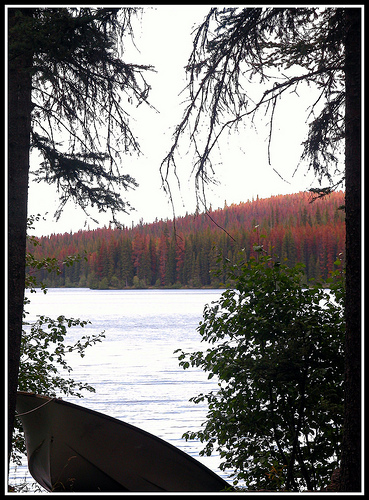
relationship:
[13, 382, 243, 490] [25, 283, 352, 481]
boat on side of lake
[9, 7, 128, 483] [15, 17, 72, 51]
trees have leaves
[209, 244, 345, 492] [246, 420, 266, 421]
bushes in background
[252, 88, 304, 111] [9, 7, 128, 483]
twigs from trees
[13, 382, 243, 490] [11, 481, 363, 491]
boat on shore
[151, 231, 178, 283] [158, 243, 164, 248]
tree with leaves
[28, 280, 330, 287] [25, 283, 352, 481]
shoreline of lake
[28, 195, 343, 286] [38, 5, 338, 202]
forest under sky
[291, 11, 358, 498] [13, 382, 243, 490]
tree on side of boat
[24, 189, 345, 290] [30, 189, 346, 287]
tree on top of hill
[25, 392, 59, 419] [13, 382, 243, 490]
rope attached to boat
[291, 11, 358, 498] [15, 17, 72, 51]
tree with leaves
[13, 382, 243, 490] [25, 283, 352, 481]
boat near lake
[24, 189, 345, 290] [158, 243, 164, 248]
tree with leaves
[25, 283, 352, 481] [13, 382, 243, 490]
lake beside boat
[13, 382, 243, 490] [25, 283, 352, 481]
boat beside lake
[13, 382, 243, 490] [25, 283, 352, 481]
boat on lake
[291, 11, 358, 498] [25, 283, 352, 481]
tree on lake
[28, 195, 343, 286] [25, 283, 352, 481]
forest on lake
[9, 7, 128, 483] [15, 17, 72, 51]
trees with leaves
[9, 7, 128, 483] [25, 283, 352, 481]
trees on lake